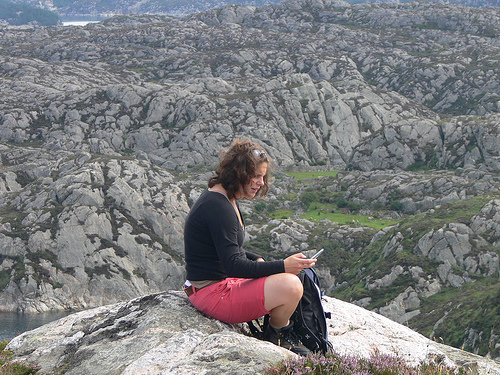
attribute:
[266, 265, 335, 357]
backpack — black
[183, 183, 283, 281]
shirt — black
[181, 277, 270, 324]
shorts — coral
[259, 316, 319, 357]
brown boot — brown  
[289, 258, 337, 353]
bag — black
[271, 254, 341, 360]
backpack — black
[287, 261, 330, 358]
backpack — black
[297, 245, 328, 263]
phone — grey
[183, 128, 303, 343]
woman — wearing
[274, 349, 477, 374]
flowers — purple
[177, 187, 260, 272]
shirt — black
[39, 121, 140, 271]
hillside — rocky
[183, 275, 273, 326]
shorts — pink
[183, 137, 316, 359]
woman — sitting, checking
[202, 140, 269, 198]
hair — brown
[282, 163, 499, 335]
foliage — green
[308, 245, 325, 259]
device — electronic